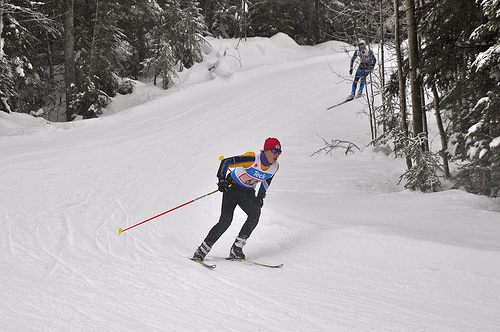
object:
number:
[238, 173, 263, 187]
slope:
[0, 38, 396, 192]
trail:
[253, 49, 338, 134]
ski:
[189, 252, 217, 267]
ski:
[222, 250, 286, 269]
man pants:
[196, 189, 261, 262]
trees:
[362, 2, 393, 150]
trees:
[453, 0, 499, 203]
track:
[402, 260, 450, 279]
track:
[196, 78, 278, 147]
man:
[192, 137, 283, 260]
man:
[342, 40, 376, 102]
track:
[89, 240, 138, 272]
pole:
[118, 188, 217, 234]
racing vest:
[231, 152, 279, 189]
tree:
[19, 6, 145, 120]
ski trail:
[311, 206, 470, 330]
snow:
[286, 169, 485, 317]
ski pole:
[353, 58, 360, 70]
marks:
[82, 236, 161, 270]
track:
[93, 257, 158, 292]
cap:
[263, 137, 281, 151]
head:
[264, 137, 282, 164]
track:
[106, 194, 184, 268]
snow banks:
[171, 32, 357, 65]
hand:
[217, 180, 231, 193]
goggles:
[264, 148, 282, 155]